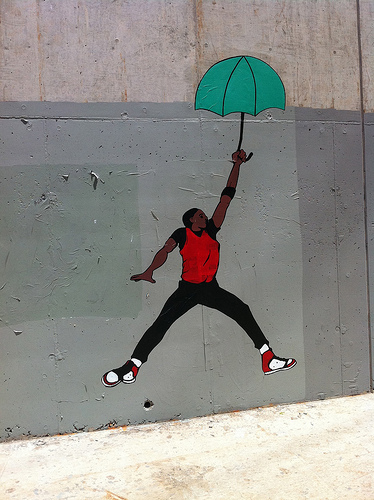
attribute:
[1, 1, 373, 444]
wall — concrete, grey, gray, painted, on building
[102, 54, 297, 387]
painting — mural, man, boy, art, umbrella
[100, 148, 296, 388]
man — jumping, painting, floating away, black, rising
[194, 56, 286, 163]
umbrella — green, painting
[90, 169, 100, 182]
nail — small, metal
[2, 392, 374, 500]
sidewalk — concrete, white, cement, light colored, in city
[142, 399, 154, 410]
hole — small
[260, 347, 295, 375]
sneaker — red, white, black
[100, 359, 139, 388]
sneaker — red, white, black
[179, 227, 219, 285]
jersey — red, tank, tank top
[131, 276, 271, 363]
pants — black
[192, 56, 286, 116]
canopy — green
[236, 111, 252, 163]
shaft — black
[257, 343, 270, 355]
sock — white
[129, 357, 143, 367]
sock — white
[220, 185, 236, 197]
band — black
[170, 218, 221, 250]
tee shirt — black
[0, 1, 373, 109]
top — unpainted